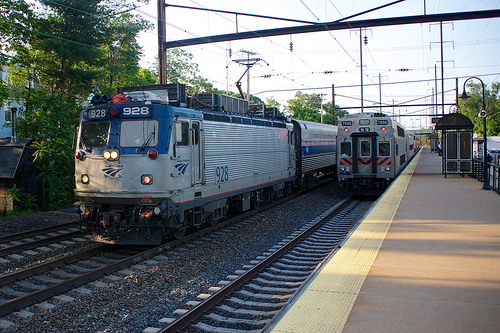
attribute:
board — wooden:
[266, 267, 310, 276]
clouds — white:
[302, 39, 332, 59]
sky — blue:
[1, 2, 498, 138]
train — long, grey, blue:
[74, 82, 337, 245]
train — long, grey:
[338, 107, 413, 197]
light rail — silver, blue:
[64, 82, 336, 250]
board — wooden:
[1, 262, 114, 328]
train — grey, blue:
[110, 111, 173, 148]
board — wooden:
[210, 270, 293, 302]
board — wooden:
[169, 298, 271, 328]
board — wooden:
[228, 261, 308, 292]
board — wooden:
[177, 294, 284, 322]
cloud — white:
[201, 1, 298, 47]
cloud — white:
[299, 39, 391, 85]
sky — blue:
[131, 0, 484, 129]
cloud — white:
[187, 1, 345, 67]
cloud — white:
[316, 41, 412, 83]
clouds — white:
[2, 1, 499, 128]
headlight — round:
[140, 171, 152, 184]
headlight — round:
[79, 175, 90, 183]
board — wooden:
[31, 269, 99, 295]